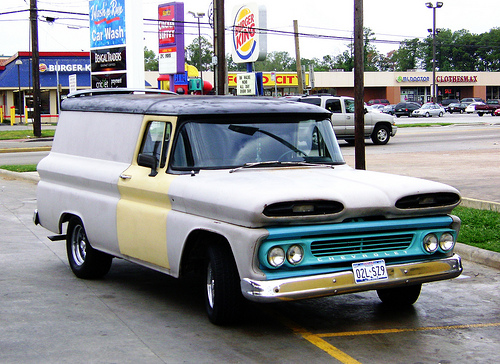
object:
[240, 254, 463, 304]
bumper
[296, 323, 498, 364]
yellow line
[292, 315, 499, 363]
parking space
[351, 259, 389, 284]
plate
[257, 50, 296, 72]
tree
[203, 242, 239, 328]
tire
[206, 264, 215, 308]
rim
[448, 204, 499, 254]
leaves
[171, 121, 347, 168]
windshield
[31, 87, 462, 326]
truck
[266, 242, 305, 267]
headlights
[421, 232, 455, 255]
headlights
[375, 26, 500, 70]
green leaves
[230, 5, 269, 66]
sign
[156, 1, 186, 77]
sign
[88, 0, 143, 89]
sign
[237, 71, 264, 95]
sign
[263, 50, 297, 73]
leaves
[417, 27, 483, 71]
tree